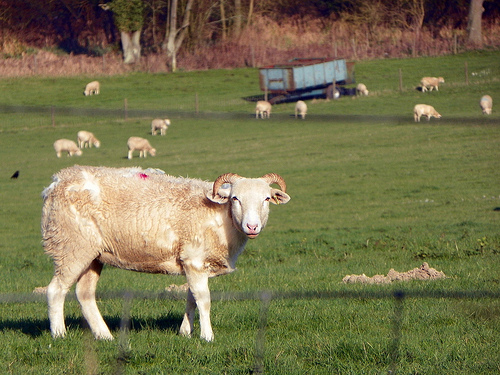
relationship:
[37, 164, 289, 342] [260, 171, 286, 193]
goat has horn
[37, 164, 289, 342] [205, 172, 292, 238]
goat has head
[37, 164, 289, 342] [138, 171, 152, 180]
goat has marking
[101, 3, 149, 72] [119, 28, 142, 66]
tree has trunk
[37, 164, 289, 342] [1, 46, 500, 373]
goat in grass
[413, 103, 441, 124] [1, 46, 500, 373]
sheep in grass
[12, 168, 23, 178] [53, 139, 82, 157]
bird facing sheep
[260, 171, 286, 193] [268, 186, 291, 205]
horn above ear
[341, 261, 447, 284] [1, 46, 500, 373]
matter on grass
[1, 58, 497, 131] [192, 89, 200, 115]
fence has pole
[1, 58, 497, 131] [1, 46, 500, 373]
fence on grass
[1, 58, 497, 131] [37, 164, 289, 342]
fence behind goat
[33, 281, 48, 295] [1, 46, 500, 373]
dirt on grass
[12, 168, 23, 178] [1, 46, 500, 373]
bird on grass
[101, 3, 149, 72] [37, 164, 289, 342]
tree behind goat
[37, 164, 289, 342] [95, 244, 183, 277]
goat has stomach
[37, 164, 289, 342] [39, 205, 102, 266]
goat has hind thigh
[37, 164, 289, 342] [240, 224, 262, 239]
goat has mouth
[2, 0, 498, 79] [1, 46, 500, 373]
foilage touching grass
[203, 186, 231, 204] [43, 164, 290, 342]
ear of goat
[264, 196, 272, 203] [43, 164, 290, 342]
eye of goat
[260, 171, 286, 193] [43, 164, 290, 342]
horn of goat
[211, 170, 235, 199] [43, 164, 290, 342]
horn of goat